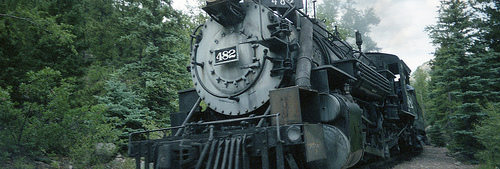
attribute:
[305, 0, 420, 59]
smoke — grey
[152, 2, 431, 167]
train — black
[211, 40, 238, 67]
numbers — white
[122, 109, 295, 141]
rail — black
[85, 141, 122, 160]
rock — Gray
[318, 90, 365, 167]
engine — grey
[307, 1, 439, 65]
smoke — hazy